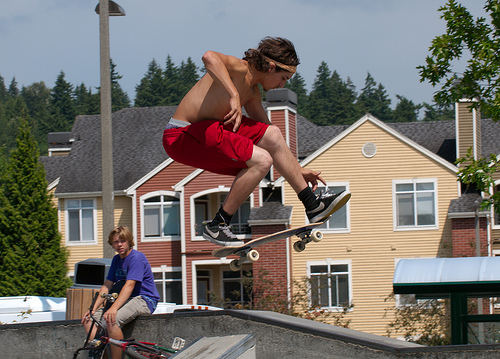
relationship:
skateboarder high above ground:
[162, 32, 353, 248] [29, 315, 426, 355]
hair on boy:
[241, 36, 302, 75] [161, 36, 351, 247]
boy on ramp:
[72, 226, 179, 359] [0, 306, 498, 357]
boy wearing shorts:
[161, 36, 351, 247] [156, 121, 273, 177]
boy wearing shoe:
[161, 36, 351, 247] [303, 190, 350, 225]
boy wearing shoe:
[161, 36, 351, 247] [194, 217, 248, 254]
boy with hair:
[161, 36, 351, 247] [242, 27, 298, 88]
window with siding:
[360, 136, 377, 161] [354, 183, 391, 248]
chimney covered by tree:
[452, 95, 483, 170] [412, 1, 497, 204]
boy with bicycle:
[105, 219, 181, 332] [72, 292, 181, 359]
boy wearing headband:
[161, 36, 351, 247] [260, 54, 299, 74]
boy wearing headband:
[161, 36, 351, 247] [247, 43, 302, 75]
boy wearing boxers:
[155, 30, 336, 253] [161, 117, 270, 175]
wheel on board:
[291, 240, 303, 250] [216, 218, 323, 270]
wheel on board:
[310, 228, 325, 243] [216, 218, 323, 270]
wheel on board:
[228, 257, 240, 272] [216, 218, 323, 270]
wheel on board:
[246, 250, 260, 262] [216, 218, 323, 270]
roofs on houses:
[48, 54, 478, 204] [273, 95, 478, 337]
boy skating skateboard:
[161, 36, 351, 247] [209, 185, 368, 271]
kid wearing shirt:
[80, 225, 161, 359] [104, 245, 160, 306]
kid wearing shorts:
[80, 225, 161, 359] [84, 291, 153, 330]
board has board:
[212, 214, 333, 271] [212, 214, 333, 271]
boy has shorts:
[161, 36, 351, 247] [162, 116, 272, 171]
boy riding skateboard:
[161, 36, 351, 247] [208, 162, 353, 268]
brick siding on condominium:
[252, 225, 292, 315] [36, 88, 500, 346]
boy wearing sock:
[161, 36, 351, 247] [293, 183, 315, 212]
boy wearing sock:
[161, 36, 351, 247] [213, 208, 242, 230]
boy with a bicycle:
[72, 226, 179, 359] [93, 313, 161, 348]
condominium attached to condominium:
[149, 142, 429, 302] [36, 88, 500, 346]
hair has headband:
[241, 36, 302, 75] [256, 51, 300, 73]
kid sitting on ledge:
[80, 225, 161, 359] [0, 306, 429, 356]